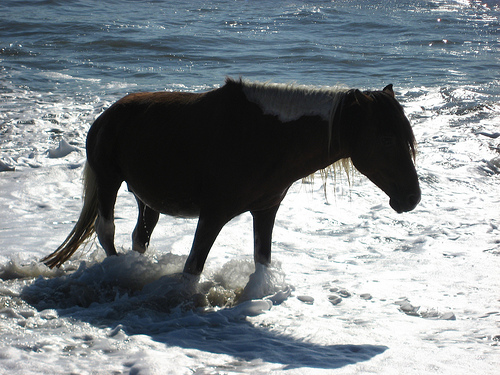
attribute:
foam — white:
[37, 67, 70, 76]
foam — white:
[11, 99, 24, 106]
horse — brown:
[44, 55, 436, 340]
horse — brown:
[106, 100, 295, 220]